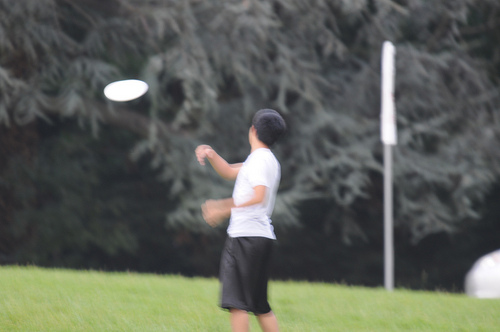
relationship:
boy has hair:
[195, 97, 279, 330] [241, 109, 289, 146]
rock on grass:
[461, 236, 499, 308] [282, 280, 497, 329]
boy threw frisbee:
[195, 97, 279, 330] [102, 65, 162, 104]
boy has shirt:
[195, 97, 279, 330] [230, 146, 286, 246]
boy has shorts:
[195, 97, 279, 330] [221, 227, 281, 324]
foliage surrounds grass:
[8, 2, 494, 282] [282, 280, 497, 329]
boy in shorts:
[195, 97, 279, 330] [221, 227, 281, 324]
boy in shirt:
[195, 97, 279, 330] [230, 146, 286, 246]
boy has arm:
[195, 97, 279, 330] [198, 183, 270, 224]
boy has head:
[195, 97, 279, 330] [244, 108, 285, 163]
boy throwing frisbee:
[195, 97, 279, 330] [102, 65, 162, 104]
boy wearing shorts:
[195, 97, 279, 330] [221, 227, 281, 324]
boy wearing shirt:
[195, 97, 279, 330] [230, 146, 286, 246]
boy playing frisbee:
[195, 97, 279, 330] [102, 65, 162, 104]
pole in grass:
[374, 145, 398, 300] [0, 262, 500, 332]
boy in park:
[195, 97, 279, 330] [2, 2, 494, 332]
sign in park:
[370, 33, 407, 156] [2, 2, 494, 332]